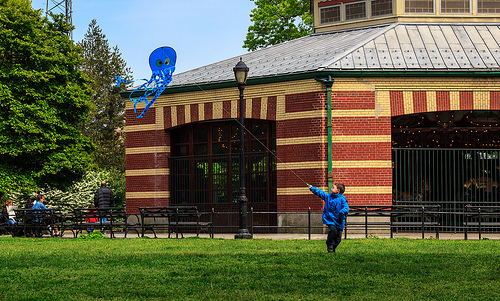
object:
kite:
[110, 45, 177, 120]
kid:
[308, 178, 350, 253]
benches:
[136, 206, 215, 237]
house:
[112, 1, 494, 237]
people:
[2, 195, 20, 225]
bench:
[2, 205, 60, 237]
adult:
[91, 180, 115, 224]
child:
[83, 202, 100, 224]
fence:
[213, 208, 499, 244]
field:
[2, 237, 499, 301]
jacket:
[307, 185, 354, 227]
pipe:
[324, 75, 334, 189]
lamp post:
[231, 54, 254, 241]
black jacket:
[93, 184, 113, 210]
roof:
[120, 22, 497, 93]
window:
[313, 1, 340, 27]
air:
[123, 4, 188, 27]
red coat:
[82, 209, 99, 223]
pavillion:
[117, 18, 499, 234]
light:
[232, 53, 252, 92]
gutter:
[281, 65, 499, 84]